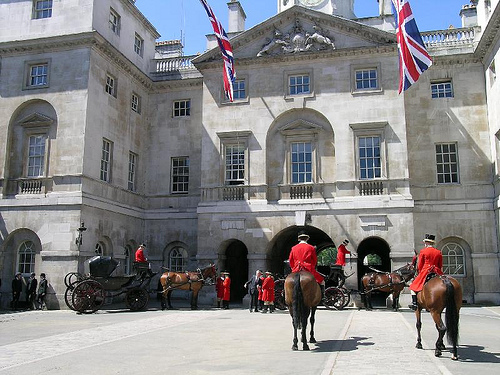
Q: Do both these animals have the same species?
A: Yes, all the animals are horses.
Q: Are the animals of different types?
A: No, all the animals are horses.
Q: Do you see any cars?
A: No, there are no cars.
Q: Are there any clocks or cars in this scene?
A: No, there are no cars or clocks.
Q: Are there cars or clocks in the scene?
A: No, there are no cars or clocks.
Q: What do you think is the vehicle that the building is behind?
A: The vehicle is a carriage.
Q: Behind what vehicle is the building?
A: The building is behind the carriage.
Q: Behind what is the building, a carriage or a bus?
A: The building is behind a carriage.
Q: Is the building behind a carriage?
A: Yes, the building is behind a carriage.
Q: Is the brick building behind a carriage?
A: Yes, the building is behind a carriage.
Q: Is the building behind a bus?
A: No, the building is behind a carriage.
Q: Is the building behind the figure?
A: Yes, the building is behind the figure.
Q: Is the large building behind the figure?
A: Yes, the building is behind the figure.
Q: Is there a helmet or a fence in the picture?
A: No, there are no fences or helmets.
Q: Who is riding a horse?
A: The man is riding a horse.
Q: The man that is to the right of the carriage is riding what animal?
A: The man is riding a horse.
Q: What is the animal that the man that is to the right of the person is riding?
A: The animal is a horse.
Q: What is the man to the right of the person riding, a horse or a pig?
A: The man is riding a horse.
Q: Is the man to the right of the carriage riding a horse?
A: Yes, the man is riding a horse.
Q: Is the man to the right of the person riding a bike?
A: No, the man is riding a horse.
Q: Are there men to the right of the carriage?
A: Yes, there is a man to the right of the carriage.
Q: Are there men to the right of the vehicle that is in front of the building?
A: Yes, there is a man to the right of the carriage.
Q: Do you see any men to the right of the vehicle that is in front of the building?
A: Yes, there is a man to the right of the carriage.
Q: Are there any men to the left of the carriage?
A: No, the man is to the right of the carriage.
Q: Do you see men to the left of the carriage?
A: No, the man is to the right of the carriage.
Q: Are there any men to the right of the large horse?
A: Yes, there is a man to the right of the horse.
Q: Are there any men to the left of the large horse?
A: No, the man is to the right of the horse.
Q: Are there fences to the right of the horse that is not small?
A: No, there is a man to the right of the horse.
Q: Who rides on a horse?
A: The man rides on a horse.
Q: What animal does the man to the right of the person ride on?
A: The man rides on a horse.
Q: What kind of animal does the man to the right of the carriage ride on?
A: The man rides on a horse.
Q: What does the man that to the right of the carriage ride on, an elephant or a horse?
A: The man rides on a horse.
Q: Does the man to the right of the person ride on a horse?
A: Yes, the man rides on a horse.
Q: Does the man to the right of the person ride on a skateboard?
A: No, the man rides on a horse.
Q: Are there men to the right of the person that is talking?
A: Yes, there is a man to the right of the person.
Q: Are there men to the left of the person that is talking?
A: No, the man is to the right of the person.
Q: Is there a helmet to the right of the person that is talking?
A: No, there is a man to the right of the person.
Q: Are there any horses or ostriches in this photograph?
A: Yes, there is a horse.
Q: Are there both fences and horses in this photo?
A: No, there is a horse but no fences.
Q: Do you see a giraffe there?
A: No, there are no giraffes.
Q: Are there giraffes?
A: No, there are no giraffes.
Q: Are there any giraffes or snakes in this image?
A: No, there are no giraffes or snakes.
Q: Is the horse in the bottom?
A: Yes, the horse is in the bottom of the image.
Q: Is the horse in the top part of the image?
A: No, the horse is in the bottom of the image.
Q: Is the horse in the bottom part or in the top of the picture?
A: The horse is in the bottom of the image.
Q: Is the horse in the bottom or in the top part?
A: The horse is in the bottom of the image.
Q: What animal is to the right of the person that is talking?
A: The animal is a horse.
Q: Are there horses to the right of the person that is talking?
A: Yes, there is a horse to the right of the person.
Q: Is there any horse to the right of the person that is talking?
A: Yes, there is a horse to the right of the person.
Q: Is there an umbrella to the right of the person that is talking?
A: No, there is a horse to the right of the person.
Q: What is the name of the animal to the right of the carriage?
A: The animal is a horse.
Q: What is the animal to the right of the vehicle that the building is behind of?
A: The animal is a horse.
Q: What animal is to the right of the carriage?
A: The animal is a horse.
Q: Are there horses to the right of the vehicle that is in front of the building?
A: Yes, there is a horse to the right of the carriage.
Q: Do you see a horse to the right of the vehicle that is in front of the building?
A: Yes, there is a horse to the right of the carriage.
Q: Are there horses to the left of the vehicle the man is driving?
A: No, the horse is to the right of the carriage.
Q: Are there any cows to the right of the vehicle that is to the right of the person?
A: No, there is a horse to the right of the carriage.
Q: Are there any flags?
A: Yes, there is a flag.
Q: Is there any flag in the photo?
A: Yes, there is a flag.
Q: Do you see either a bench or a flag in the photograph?
A: Yes, there is a flag.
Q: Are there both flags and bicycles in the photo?
A: No, there is a flag but no bicycles.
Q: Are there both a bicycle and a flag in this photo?
A: No, there is a flag but no bicycles.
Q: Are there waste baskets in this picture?
A: No, there are no waste baskets.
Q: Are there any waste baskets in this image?
A: No, there are no waste baskets.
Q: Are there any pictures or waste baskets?
A: No, there are no waste baskets or pictures.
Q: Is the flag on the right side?
A: Yes, the flag is on the right of the image.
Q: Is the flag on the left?
A: No, the flag is on the right of the image.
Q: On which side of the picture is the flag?
A: The flag is on the right of the image.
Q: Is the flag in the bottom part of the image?
A: No, the flag is in the top of the image.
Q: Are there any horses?
A: Yes, there is a horse.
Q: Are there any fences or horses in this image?
A: Yes, there is a horse.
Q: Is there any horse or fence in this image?
A: Yes, there is a horse.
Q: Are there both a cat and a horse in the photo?
A: No, there is a horse but no cats.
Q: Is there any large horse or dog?
A: Yes, there is a large horse.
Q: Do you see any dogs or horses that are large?
A: Yes, the horse is large.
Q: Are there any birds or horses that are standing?
A: Yes, the horse is standing.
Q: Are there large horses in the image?
A: Yes, there is a large horse.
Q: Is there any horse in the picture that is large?
A: Yes, there is a horse that is large.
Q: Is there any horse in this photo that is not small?
A: Yes, there is a large horse.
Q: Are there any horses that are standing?
A: Yes, there is a horse that is standing.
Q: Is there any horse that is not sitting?
A: Yes, there is a horse that is standing.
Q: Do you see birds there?
A: No, there are no birds.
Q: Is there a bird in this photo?
A: No, there are no birds.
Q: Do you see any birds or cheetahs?
A: No, there are no birds or cheetahs.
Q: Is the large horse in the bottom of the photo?
A: Yes, the horse is in the bottom of the image.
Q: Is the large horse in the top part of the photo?
A: No, the horse is in the bottom of the image.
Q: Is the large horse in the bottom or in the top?
A: The horse is in the bottom of the image.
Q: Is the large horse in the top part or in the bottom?
A: The horse is in the bottom of the image.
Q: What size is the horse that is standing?
A: The horse is large.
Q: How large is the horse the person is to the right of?
A: The horse is large.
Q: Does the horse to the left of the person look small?
A: No, the horse is large.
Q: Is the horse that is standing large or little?
A: The horse is large.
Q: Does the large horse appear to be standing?
A: Yes, the horse is standing.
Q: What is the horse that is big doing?
A: The horse is standing.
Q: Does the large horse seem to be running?
A: No, the horse is standing.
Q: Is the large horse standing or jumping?
A: The horse is standing.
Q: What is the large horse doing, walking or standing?
A: The horse is standing.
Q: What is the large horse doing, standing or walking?
A: The horse is standing.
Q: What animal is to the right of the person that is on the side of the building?
A: The animal is a horse.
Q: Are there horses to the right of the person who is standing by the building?
A: Yes, there is a horse to the right of the person.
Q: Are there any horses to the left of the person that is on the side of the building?
A: No, the horse is to the right of the person.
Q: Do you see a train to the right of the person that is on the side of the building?
A: No, there is a horse to the right of the person.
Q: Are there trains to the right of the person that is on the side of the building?
A: No, there is a horse to the right of the person.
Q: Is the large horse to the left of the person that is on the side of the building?
A: No, the horse is to the right of the person.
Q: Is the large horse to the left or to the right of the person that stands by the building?
A: The horse is to the right of the person.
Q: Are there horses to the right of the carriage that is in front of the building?
A: Yes, there is a horse to the right of the carriage.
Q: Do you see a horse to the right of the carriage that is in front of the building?
A: Yes, there is a horse to the right of the carriage.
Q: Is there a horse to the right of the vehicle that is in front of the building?
A: Yes, there is a horse to the right of the carriage.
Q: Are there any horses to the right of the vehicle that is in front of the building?
A: Yes, there is a horse to the right of the carriage.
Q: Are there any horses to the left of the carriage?
A: No, the horse is to the right of the carriage.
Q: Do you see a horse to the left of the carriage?
A: No, the horse is to the right of the carriage.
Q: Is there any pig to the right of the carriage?
A: No, there is a horse to the right of the carriage.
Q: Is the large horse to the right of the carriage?
A: Yes, the horse is to the right of the carriage.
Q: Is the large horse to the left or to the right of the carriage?
A: The horse is to the right of the carriage.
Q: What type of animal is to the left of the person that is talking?
A: The animal is a horse.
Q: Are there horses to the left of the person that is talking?
A: Yes, there is a horse to the left of the person.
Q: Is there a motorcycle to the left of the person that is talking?
A: No, there is a horse to the left of the person.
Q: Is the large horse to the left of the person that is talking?
A: Yes, the horse is to the left of the person.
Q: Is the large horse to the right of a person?
A: No, the horse is to the left of a person.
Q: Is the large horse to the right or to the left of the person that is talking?
A: The horse is to the left of the person.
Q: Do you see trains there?
A: No, there are no trains.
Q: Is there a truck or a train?
A: No, there are no trains or trucks.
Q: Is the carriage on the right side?
A: No, the carriage is on the left of the image.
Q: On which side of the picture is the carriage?
A: The carriage is on the left of the image.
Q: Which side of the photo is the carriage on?
A: The carriage is on the left of the image.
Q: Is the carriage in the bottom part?
A: Yes, the carriage is in the bottom of the image.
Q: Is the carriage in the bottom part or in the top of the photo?
A: The carriage is in the bottom of the image.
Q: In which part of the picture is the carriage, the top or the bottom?
A: The carriage is in the bottom of the image.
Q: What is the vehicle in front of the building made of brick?
A: The vehicle is a carriage.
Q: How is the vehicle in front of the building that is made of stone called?
A: The vehicle is a carriage.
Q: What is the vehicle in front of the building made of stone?
A: The vehicle is a carriage.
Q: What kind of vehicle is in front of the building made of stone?
A: The vehicle is a carriage.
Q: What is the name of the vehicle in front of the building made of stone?
A: The vehicle is a carriage.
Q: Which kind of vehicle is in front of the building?
A: The vehicle is a carriage.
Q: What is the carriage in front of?
A: The carriage is in front of the building.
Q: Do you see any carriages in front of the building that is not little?
A: Yes, there is a carriage in front of the building.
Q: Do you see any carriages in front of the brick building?
A: Yes, there is a carriage in front of the building.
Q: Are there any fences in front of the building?
A: No, there is a carriage in front of the building.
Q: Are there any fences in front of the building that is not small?
A: No, there is a carriage in front of the building.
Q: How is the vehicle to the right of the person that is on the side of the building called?
A: The vehicle is a carriage.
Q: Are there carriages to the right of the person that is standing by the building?
A: Yes, there is a carriage to the right of the person.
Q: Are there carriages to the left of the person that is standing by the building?
A: No, the carriage is to the right of the person.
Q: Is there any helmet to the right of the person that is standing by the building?
A: No, there is a carriage to the right of the person.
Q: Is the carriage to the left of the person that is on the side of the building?
A: No, the carriage is to the right of the person.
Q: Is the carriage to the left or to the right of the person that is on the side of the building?
A: The carriage is to the right of the person.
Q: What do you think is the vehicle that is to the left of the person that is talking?
A: The vehicle is a carriage.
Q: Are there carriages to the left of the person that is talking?
A: Yes, there is a carriage to the left of the person.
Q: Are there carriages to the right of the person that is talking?
A: No, the carriage is to the left of the person.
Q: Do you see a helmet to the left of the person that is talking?
A: No, there is a carriage to the left of the person.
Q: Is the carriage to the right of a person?
A: No, the carriage is to the left of a person.